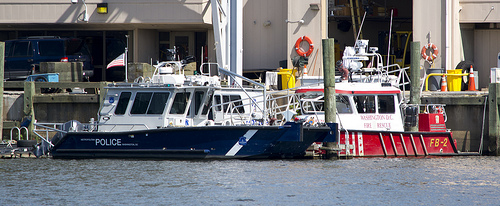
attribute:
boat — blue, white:
[47, 64, 351, 165]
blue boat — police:
[48, 42, 335, 163]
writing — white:
[90, 134, 124, 148]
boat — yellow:
[56, 73, 430, 160]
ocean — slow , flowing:
[0, 156, 497, 204]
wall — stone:
[10, 2, 226, 28]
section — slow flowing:
[196, 167, 409, 202]